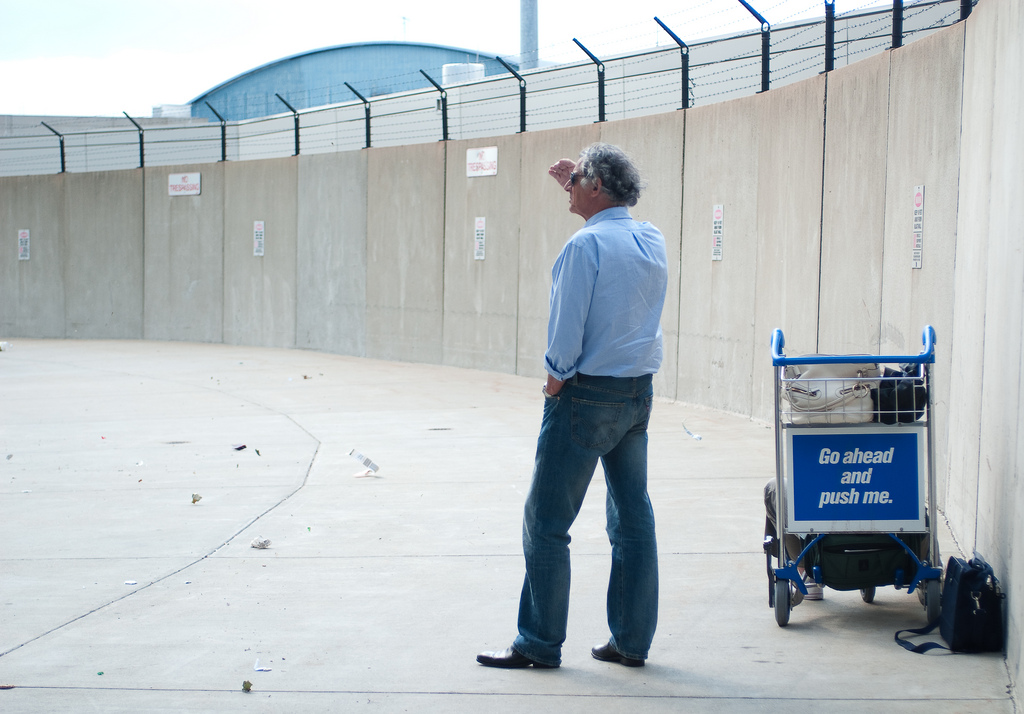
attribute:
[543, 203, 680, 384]
shirt — blue, long sleeved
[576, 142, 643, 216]
hair — gray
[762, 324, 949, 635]
luggage cart — white, blue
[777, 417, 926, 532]
sign — blue, white